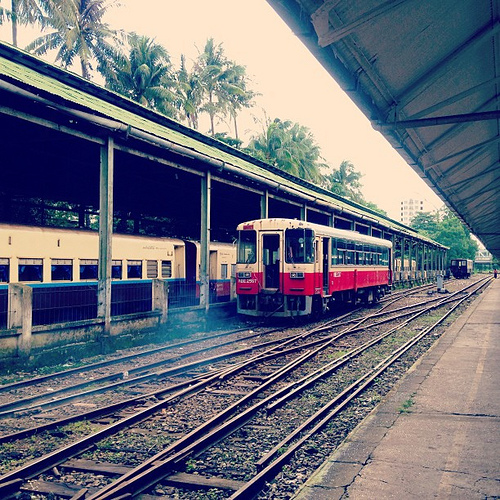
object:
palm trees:
[0, 1, 120, 85]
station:
[0, 1, 500, 499]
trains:
[236, 214, 397, 324]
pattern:
[235, 268, 392, 300]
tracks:
[225, 275, 498, 499]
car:
[450, 257, 472, 282]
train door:
[260, 227, 284, 291]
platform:
[277, 273, 498, 500]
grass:
[0, 274, 472, 498]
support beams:
[198, 164, 214, 313]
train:
[0, 219, 187, 332]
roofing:
[268, 1, 499, 269]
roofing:
[1, 36, 452, 258]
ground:
[2, 271, 500, 499]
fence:
[0, 274, 239, 359]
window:
[234, 225, 261, 266]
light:
[285, 269, 309, 281]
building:
[397, 192, 439, 228]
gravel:
[2, 275, 492, 499]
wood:
[1, 268, 235, 360]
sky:
[0, 0, 452, 221]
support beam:
[93, 139, 115, 324]